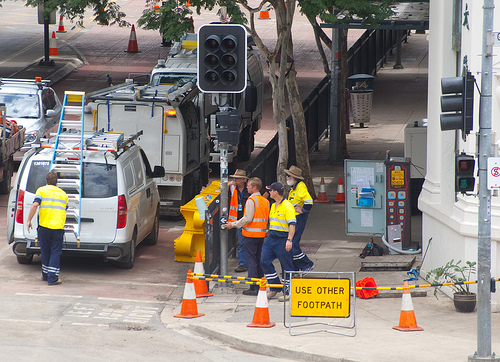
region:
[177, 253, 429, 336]
orange and white traffic cones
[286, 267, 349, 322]
a yellow and black sign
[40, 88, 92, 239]
blue ladder on the back of a truck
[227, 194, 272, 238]
orange vests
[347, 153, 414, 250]
a control box on the street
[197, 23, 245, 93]
traffic signal on the side of the road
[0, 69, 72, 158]
a silver car stopped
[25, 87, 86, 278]
man getting a ladder from the van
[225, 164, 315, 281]
four men standing on the side of the road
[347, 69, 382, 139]
small garbage can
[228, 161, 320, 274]
men wearing reflective vest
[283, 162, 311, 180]
a hat the guy is wearing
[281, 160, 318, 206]
a guy with a white beard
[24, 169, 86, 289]
a guy holding a ladder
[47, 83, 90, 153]
a ladder on top of the van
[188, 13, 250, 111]
a non-working traffic light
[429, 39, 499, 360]
traffic lights attached to the pole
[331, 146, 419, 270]
a utility box that is open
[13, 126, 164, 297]
a white utility van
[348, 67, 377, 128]
a trash bin on the sidewalk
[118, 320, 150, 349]
part of a roasd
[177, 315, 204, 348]
edge of a road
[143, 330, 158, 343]
part of a road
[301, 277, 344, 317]
part of a banner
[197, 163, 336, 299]
four men standing on sidewalk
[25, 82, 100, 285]
man loading ladder on van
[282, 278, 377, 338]
yellow sign with black lettering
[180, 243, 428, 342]
four orange and white safety cones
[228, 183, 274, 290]
man wearing orange safety vest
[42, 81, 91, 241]
blue and yellow ladder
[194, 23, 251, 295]
black traffic light beside man in orange vest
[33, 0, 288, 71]
orange safety cones up street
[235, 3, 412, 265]
black fencing along sidewalk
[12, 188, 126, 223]
back tail lights of white van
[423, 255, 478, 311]
a green plant in a planter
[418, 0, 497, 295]
the wall of a white building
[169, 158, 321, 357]
construction workers near a curb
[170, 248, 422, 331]
orange and white traffic cones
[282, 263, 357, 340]
yellow warning sign to avoid area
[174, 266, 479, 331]
caution tape looped around cones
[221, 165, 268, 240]
two men wearing orange reflective vests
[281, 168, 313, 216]
worker with a bushy white beard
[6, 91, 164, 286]
man reaching towards ladder on back of van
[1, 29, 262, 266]
road work vehicles parked in close proximity to each other